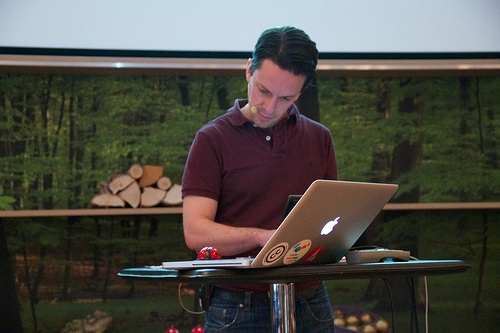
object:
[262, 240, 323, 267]
stickers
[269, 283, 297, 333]
leg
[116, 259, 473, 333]
table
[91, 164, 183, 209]
wood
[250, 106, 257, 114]
microphone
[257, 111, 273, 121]
mouth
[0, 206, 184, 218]
shelf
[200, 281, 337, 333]
jeans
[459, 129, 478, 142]
leaf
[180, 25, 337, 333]
man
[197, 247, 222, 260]
ladybug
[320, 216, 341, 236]
apple logo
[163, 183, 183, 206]
fire wood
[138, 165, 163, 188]
fire wood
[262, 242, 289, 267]
sticker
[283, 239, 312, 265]
sticker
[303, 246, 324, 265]
sticker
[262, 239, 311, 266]
stickers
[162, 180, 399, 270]
computer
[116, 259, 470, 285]
podium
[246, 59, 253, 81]
ear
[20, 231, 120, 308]
green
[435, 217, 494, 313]
green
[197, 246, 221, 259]
red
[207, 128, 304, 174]
purple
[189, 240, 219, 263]
mouse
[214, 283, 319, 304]
belt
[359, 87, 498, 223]
green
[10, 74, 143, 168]
green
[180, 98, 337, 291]
polo shirt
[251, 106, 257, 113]
microphone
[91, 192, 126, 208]
fire wood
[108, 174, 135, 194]
fire wood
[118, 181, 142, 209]
fire wood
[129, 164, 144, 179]
fire wood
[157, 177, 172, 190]
fire wood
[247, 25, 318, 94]
hair